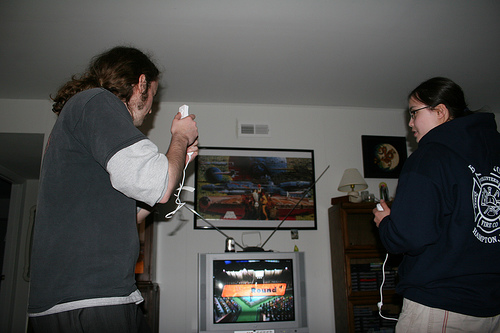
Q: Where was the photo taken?
A: A living room.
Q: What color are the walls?
A: White.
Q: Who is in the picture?
A: Two people.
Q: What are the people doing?
A: Playing a game.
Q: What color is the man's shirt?
A: Gray.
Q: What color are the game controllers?
A: White.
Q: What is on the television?
A: A game.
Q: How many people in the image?
A: Two.